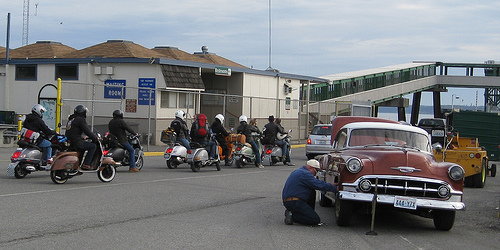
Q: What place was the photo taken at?
A: It was taken at the sidewalk.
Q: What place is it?
A: It is a sidewalk.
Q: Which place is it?
A: It is a sidewalk.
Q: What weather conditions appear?
A: It is clear.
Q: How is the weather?
A: It is clear.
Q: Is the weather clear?
A: Yes, it is clear.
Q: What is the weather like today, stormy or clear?
A: It is clear.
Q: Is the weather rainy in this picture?
A: No, it is clear.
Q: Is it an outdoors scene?
A: Yes, it is outdoors.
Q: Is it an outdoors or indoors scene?
A: It is outdoors.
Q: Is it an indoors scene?
A: No, it is outdoors.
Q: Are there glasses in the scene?
A: No, there are no glasses.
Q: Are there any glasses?
A: No, there are no glasses.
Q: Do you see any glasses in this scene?
A: No, there are no glasses.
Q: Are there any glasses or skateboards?
A: No, there are no glasses or skateboards.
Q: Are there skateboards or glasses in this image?
A: No, there are no glasses or skateboards.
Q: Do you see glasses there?
A: No, there are no glasses.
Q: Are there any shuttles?
A: No, there are no shuttles.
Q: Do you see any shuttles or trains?
A: No, there are no shuttles or trains.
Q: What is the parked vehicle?
A: The vehicle is a car.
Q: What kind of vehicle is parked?
A: The vehicle is a car.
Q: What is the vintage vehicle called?
A: The vehicle is a car.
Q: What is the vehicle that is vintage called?
A: The vehicle is a car.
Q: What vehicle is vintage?
A: The vehicle is a car.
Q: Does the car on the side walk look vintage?
A: Yes, the car is vintage.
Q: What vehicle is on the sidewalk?
A: The vehicle is a car.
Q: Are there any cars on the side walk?
A: Yes, there is a car on the side walk.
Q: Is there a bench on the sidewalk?
A: No, there is a car on the sidewalk.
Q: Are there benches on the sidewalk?
A: No, there is a car on the sidewalk.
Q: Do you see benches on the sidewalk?
A: No, there is a car on the sidewalk.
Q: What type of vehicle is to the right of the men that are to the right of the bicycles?
A: The vehicle is a car.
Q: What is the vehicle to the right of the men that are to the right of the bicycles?
A: The vehicle is a car.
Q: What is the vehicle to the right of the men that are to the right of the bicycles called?
A: The vehicle is a car.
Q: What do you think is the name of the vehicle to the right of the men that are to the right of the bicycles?
A: The vehicle is a car.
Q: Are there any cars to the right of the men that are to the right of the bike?
A: Yes, there is a car to the right of the men.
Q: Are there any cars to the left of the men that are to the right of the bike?
A: No, the car is to the right of the men.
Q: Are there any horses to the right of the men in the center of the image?
A: No, there is a car to the right of the men.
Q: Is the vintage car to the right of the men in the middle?
A: Yes, the car is to the right of the men.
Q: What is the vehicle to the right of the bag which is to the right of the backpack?
A: The vehicle is a car.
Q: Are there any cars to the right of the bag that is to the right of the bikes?
A: Yes, there is a car to the right of the bag.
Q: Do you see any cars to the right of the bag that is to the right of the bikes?
A: Yes, there is a car to the right of the bag.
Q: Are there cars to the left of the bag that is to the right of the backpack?
A: No, the car is to the right of the bag.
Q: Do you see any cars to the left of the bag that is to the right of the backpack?
A: No, the car is to the right of the bag.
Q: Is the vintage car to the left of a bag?
A: No, the car is to the right of a bag.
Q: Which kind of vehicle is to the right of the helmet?
A: The vehicle is a car.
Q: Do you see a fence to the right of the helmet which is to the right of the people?
A: No, there is a car to the right of the helmet.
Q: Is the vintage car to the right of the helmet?
A: Yes, the car is to the right of the helmet.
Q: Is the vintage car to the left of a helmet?
A: No, the car is to the right of a helmet.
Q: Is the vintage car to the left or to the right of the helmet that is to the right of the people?
A: The car is to the right of the helmet.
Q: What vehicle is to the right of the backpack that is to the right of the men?
A: The vehicle is a car.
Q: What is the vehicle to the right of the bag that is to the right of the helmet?
A: The vehicle is a car.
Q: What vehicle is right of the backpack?
A: The vehicle is a car.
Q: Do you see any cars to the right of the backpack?
A: Yes, there is a car to the right of the backpack.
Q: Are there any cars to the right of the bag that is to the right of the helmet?
A: Yes, there is a car to the right of the backpack.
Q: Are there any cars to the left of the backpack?
A: No, the car is to the right of the backpack.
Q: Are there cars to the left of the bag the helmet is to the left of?
A: No, the car is to the right of the backpack.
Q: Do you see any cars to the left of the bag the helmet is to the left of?
A: No, the car is to the right of the backpack.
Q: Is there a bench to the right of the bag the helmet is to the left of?
A: No, there is a car to the right of the backpack.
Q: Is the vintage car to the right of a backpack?
A: Yes, the car is to the right of a backpack.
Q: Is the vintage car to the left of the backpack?
A: No, the car is to the right of the backpack.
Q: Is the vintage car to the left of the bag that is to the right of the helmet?
A: No, the car is to the right of the backpack.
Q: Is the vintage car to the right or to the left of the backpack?
A: The car is to the right of the backpack.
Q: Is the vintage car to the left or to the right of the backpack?
A: The car is to the right of the backpack.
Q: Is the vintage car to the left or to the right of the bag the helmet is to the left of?
A: The car is to the right of the backpack.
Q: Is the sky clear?
A: Yes, the sky is clear.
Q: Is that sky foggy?
A: No, the sky is clear.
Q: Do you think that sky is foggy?
A: No, the sky is clear.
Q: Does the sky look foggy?
A: No, the sky is clear.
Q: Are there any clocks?
A: No, there are no clocks.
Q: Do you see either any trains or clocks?
A: No, there are no clocks or trains.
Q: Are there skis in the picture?
A: No, there are no skis.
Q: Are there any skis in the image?
A: No, there are no skis.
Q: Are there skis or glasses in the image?
A: No, there are no skis or glasses.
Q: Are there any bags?
A: Yes, there is a bag.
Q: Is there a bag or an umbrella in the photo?
A: Yes, there is a bag.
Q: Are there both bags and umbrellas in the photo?
A: No, there is a bag but no umbrellas.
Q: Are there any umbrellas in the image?
A: No, there are no umbrellas.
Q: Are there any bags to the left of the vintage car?
A: Yes, there is a bag to the left of the car.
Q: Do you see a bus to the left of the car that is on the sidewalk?
A: No, there is a bag to the left of the car.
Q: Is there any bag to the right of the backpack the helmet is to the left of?
A: Yes, there is a bag to the right of the backpack.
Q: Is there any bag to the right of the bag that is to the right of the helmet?
A: Yes, there is a bag to the right of the backpack.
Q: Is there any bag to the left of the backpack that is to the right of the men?
A: No, the bag is to the right of the backpack.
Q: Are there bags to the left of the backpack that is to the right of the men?
A: No, the bag is to the right of the backpack.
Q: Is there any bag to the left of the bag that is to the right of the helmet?
A: No, the bag is to the right of the backpack.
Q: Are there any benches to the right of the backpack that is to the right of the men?
A: No, there is a bag to the right of the backpack.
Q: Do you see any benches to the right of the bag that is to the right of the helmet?
A: No, there is a bag to the right of the backpack.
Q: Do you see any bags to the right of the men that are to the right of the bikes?
A: Yes, there is a bag to the right of the men.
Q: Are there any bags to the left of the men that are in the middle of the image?
A: No, the bag is to the right of the men.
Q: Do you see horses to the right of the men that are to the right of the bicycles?
A: No, there is a bag to the right of the men.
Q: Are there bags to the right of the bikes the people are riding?
A: Yes, there is a bag to the right of the bikes.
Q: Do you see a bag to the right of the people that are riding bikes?
A: Yes, there is a bag to the right of the people.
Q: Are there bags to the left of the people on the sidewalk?
A: No, the bag is to the right of the people.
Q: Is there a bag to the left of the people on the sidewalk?
A: No, the bag is to the right of the people.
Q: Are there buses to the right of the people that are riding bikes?
A: No, there is a bag to the right of the people.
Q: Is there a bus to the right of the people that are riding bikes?
A: No, there is a bag to the right of the people.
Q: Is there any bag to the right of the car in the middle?
A: No, the bag is to the left of the car.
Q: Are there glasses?
A: No, there are no glasses.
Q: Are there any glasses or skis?
A: No, there are no glasses or skis.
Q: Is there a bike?
A: Yes, there is a bike.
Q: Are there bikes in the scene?
A: Yes, there is a bike.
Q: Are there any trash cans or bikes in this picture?
A: Yes, there is a bike.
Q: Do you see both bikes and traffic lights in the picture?
A: No, there is a bike but no traffic lights.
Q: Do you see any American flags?
A: No, there are no American flags.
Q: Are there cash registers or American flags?
A: No, there are no American flags or cash registers.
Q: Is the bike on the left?
A: Yes, the bike is on the left of the image.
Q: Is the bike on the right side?
A: No, the bike is on the left of the image.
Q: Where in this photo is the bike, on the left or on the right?
A: The bike is on the left of the image.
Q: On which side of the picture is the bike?
A: The bike is on the left of the image.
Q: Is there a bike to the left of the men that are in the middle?
A: Yes, there is a bike to the left of the men.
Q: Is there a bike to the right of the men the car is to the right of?
A: No, the bike is to the left of the men.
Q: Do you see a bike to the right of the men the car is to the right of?
A: No, the bike is to the left of the men.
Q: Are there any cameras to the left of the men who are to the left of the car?
A: No, there is a bike to the left of the men.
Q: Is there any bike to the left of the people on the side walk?
A: Yes, there is a bike to the left of the people.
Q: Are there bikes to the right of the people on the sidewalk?
A: No, the bike is to the left of the people.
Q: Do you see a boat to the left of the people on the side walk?
A: No, there is a bike to the left of the people.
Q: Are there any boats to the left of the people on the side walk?
A: No, there is a bike to the left of the people.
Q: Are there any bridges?
A: Yes, there is a bridge.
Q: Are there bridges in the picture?
A: Yes, there is a bridge.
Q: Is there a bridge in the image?
A: Yes, there is a bridge.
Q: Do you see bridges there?
A: Yes, there is a bridge.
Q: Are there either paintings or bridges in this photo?
A: Yes, there is a bridge.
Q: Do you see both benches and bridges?
A: No, there is a bridge but no benches.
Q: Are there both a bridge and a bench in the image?
A: No, there is a bridge but no benches.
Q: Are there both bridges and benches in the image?
A: No, there is a bridge but no benches.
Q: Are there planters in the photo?
A: No, there are no planters.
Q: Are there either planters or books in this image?
A: No, there are no planters or books.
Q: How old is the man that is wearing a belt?
A: The man is old.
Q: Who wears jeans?
A: The man wears jeans.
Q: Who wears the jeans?
A: The man wears jeans.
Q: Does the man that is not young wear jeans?
A: Yes, the man wears jeans.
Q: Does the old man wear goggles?
A: No, the man wears jeans.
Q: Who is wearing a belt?
A: The man is wearing a belt.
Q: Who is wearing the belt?
A: The man is wearing a belt.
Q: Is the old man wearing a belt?
A: Yes, the man is wearing a belt.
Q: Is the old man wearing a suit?
A: No, the man is wearing a belt.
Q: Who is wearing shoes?
A: The man is wearing shoes.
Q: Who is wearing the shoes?
A: The man is wearing shoes.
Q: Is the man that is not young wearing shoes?
A: Yes, the man is wearing shoes.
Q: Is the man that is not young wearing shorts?
A: No, the man is wearing shoes.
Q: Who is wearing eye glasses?
A: The man is wearing eye glasses.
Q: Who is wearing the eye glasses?
A: The man is wearing eye glasses.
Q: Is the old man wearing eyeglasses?
A: Yes, the man is wearing eyeglasses.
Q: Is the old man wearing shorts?
A: No, the man is wearing eyeglasses.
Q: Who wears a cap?
A: The man wears a cap.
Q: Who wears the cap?
A: The man wears a cap.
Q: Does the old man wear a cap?
A: Yes, the man wears a cap.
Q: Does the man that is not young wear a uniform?
A: No, the man wears a cap.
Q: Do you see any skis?
A: No, there are no skis.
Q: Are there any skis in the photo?
A: No, there are no skis.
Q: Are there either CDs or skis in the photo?
A: No, there are no skis or cds.